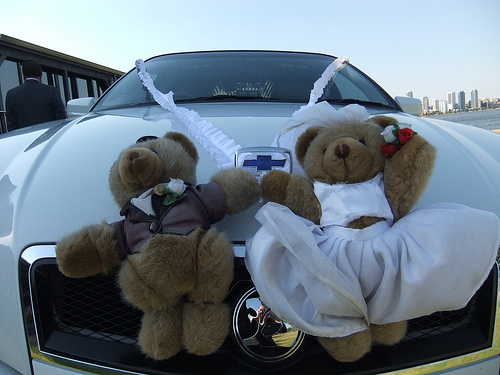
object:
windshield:
[89, 50, 403, 111]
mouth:
[123, 166, 156, 185]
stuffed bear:
[259, 115, 437, 362]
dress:
[244, 172, 500, 338]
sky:
[338, 0, 499, 46]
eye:
[322, 147, 327, 154]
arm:
[56, 221, 128, 278]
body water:
[463, 114, 497, 122]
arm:
[263, 169, 323, 225]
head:
[107, 131, 199, 208]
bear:
[56, 131, 262, 360]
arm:
[195, 168, 263, 216]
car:
[0, 49, 500, 375]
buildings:
[421, 89, 489, 113]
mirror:
[393, 97, 424, 118]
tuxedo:
[106, 177, 225, 257]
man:
[4, 56, 67, 133]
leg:
[181, 235, 234, 356]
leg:
[115, 258, 182, 360]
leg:
[314, 326, 373, 362]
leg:
[370, 319, 407, 346]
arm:
[385, 129, 436, 214]